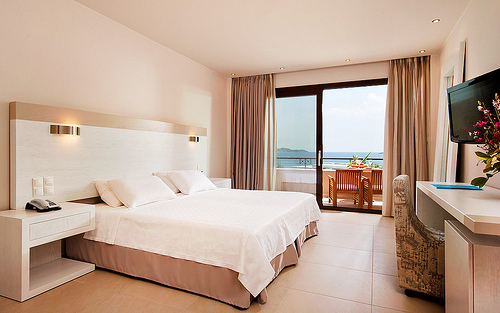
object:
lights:
[70, 125, 76, 134]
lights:
[189, 136, 197, 143]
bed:
[66, 165, 324, 310]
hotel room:
[0, 0, 500, 313]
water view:
[277, 136, 384, 169]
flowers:
[482, 119, 490, 127]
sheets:
[225, 244, 230, 248]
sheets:
[206, 217, 209, 220]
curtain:
[229, 72, 276, 191]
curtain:
[381, 53, 432, 217]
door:
[315, 77, 402, 214]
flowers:
[492, 133, 499, 139]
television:
[443, 67, 500, 143]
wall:
[438, 0, 500, 190]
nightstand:
[0, 196, 98, 303]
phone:
[23, 197, 61, 213]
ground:
[0, 189, 500, 313]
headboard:
[7, 98, 217, 209]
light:
[189, 136, 200, 143]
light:
[48, 123, 83, 137]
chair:
[390, 172, 446, 301]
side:
[327, 168, 365, 209]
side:
[369, 167, 386, 207]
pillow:
[105, 173, 179, 210]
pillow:
[94, 181, 125, 208]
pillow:
[150, 169, 180, 195]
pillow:
[165, 168, 220, 195]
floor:
[0, 199, 445, 313]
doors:
[274, 83, 324, 189]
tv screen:
[448, 79, 500, 143]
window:
[274, 78, 390, 216]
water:
[296, 156, 309, 164]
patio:
[275, 84, 399, 201]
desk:
[414, 180, 500, 311]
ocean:
[275, 152, 384, 168]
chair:
[327, 168, 365, 209]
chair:
[362, 168, 383, 209]